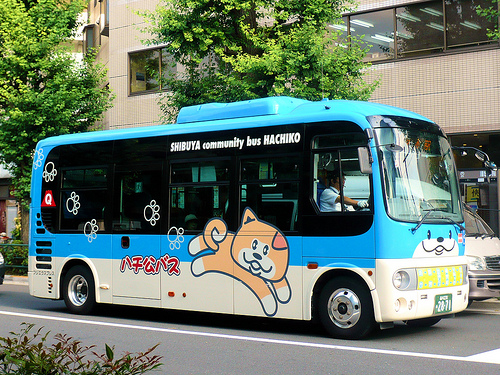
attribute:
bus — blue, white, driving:
[30, 96, 470, 339]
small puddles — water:
[114, 178, 136, 251]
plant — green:
[130, 0, 385, 106]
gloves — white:
[353, 190, 369, 210]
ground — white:
[457, 102, 497, 137]